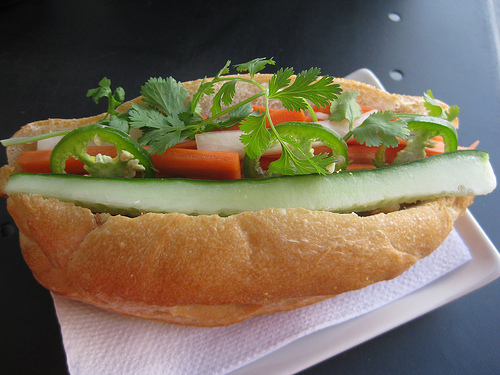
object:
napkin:
[93, 333, 210, 362]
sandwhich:
[0, 72, 493, 328]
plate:
[20, 69, 500, 373]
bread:
[7, 72, 475, 325]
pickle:
[3, 151, 498, 212]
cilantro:
[0, 66, 347, 174]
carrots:
[18, 145, 245, 178]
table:
[0, 0, 498, 374]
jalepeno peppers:
[244, 123, 348, 176]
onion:
[195, 109, 378, 159]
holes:
[389, 70, 404, 83]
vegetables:
[336, 84, 406, 145]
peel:
[7, 148, 488, 212]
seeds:
[130, 165, 144, 170]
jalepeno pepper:
[48, 124, 155, 180]